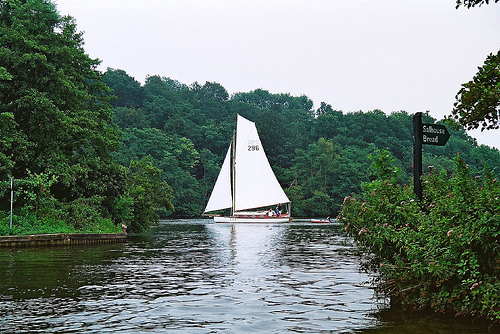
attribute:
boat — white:
[200, 115, 292, 222]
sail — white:
[236, 110, 290, 210]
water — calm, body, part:
[2, 218, 500, 332]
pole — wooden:
[413, 110, 424, 200]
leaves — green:
[1, 2, 130, 200]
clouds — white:
[54, 1, 500, 151]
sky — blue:
[51, 0, 497, 150]